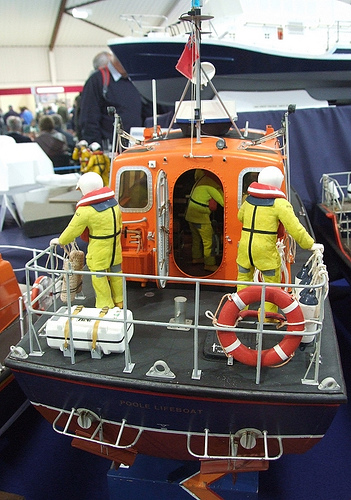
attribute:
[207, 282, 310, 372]
lifesaver — red, orange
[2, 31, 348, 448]
boat — gray, blue, black orange, orange, figurine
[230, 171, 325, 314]
worker — wearing yellow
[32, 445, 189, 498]
floor — blue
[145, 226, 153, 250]
handles — secured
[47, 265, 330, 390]
deck — grey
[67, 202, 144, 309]
crew suit — green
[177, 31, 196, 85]
flag — red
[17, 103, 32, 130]
person — wearing blue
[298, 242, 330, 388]
railing — metal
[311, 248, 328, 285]
rope — white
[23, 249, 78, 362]
rail — gray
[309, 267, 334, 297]
metal ring — gray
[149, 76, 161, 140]
vase — clear